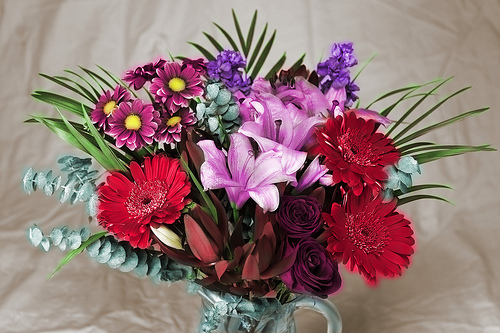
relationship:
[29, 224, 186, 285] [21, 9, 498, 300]
blue plant in arrangement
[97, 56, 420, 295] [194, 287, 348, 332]
flower in vase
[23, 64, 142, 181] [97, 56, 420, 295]
leaves behind flower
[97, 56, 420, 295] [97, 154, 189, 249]
flower inside flower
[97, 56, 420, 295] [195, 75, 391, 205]
flower inside flower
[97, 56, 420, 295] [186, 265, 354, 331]
flower in vase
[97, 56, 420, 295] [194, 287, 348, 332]
flower are in vase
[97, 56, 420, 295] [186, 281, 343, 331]
flower in pitcher vase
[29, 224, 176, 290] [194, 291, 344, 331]
blue plant in vase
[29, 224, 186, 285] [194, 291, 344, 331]
blue plant in vase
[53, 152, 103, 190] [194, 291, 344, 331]
blue plant in vase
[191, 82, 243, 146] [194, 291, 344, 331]
blue plant in vase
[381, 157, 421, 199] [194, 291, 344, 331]
blue plant in vase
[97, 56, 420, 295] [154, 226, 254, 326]
flower are in vase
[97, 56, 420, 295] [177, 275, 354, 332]
flower are in vase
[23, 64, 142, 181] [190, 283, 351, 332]
leaves are in vase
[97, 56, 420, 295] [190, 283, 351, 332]
flower in vase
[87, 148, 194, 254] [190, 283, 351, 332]
flower in vase